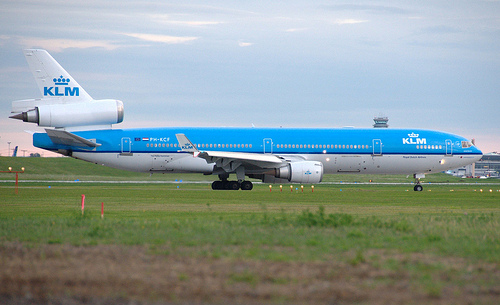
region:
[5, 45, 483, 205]
a jet ready for take off at the airport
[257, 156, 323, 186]
jet engines are on the wing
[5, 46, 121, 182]
the tail of the plane has a jet engine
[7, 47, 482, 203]
the plane is blue and white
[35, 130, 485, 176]
a dark blue stripe is along side the plane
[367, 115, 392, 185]
the airport tower is behind the plane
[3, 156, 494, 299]
the grass is green and brown on the field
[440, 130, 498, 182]
the airline terminal is in the background of the plane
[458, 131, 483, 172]
the cockpit of the plane has windows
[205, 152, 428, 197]
the wheels are down on the jet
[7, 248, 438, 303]
Brown dry surface in the foreground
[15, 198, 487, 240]
Green grass beneath the plane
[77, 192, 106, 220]
Two red markers in the ground close together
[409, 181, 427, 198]
Small wheels beneath the front of the plane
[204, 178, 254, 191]
Wheels beneath the plane's midsection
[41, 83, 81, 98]
KLM written in blue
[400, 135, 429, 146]
KLM written in white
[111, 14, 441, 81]
Sky above the plane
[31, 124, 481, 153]
Bright blue portion of the plane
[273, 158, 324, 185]
Engine on the side of the plane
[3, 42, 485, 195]
this is a plane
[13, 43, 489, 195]
the plane is blue in color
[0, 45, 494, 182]
the plane is parked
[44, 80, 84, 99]
the plane is written klm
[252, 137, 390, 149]
the doors are closed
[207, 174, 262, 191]
the wheels are on the ground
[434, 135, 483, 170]
the plane has a streamlined head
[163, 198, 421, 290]
the grass is short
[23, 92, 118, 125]
the fan is white in color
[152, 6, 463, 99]
the sky is grey in color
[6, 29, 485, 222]
large blue and white plane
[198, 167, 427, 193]
black wheels under large plane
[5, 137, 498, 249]
green grass bounding runway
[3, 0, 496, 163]
clear blue cloudy sky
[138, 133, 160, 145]
small red and white flag on plane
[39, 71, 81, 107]
blue letters on white tail spelling KLM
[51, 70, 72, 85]
blue crown on white tail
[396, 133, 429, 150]
white letter on blue nose spelling KLM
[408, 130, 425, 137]
white crown on blue nose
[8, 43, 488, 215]
large plane taking off at airport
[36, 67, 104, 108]
KLM in blue on the plane.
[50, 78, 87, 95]
A crown on the plane.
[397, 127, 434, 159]
KLM in white on the plane.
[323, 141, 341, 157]
Windows on the plane.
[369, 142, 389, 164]
Door on the plane.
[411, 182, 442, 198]
The wheel is down.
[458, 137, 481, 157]
Cockpit of the plane.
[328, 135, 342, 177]
The plane is blue and white.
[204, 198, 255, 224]
The grass is green.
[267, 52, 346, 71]
The sky is blue.